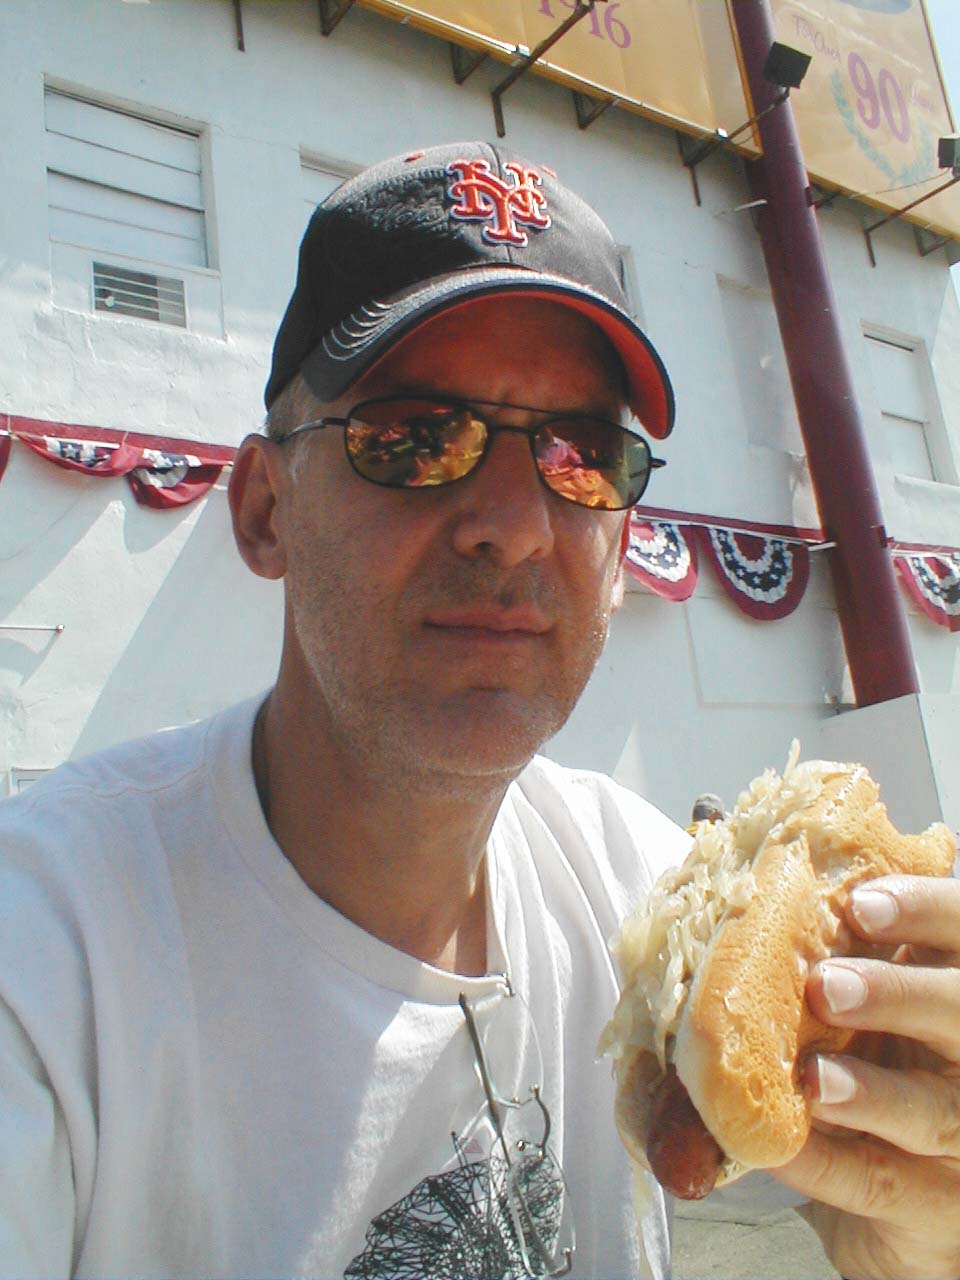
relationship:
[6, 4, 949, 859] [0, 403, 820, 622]
wall has patriotic bunting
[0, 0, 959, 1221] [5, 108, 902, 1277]
wall behind man